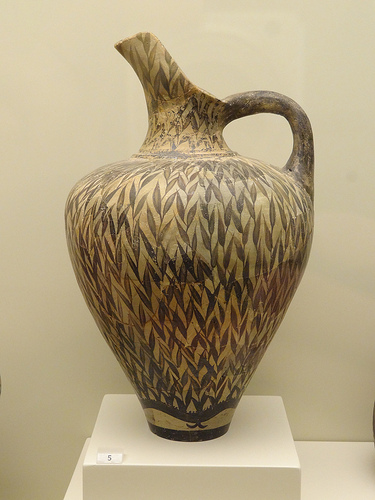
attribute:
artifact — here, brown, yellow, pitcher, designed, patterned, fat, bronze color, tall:
[40, 48, 338, 451]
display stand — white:
[95, 444, 299, 493]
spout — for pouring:
[113, 33, 176, 92]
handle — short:
[226, 95, 321, 173]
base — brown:
[121, 393, 259, 453]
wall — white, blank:
[292, 25, 336, 53]